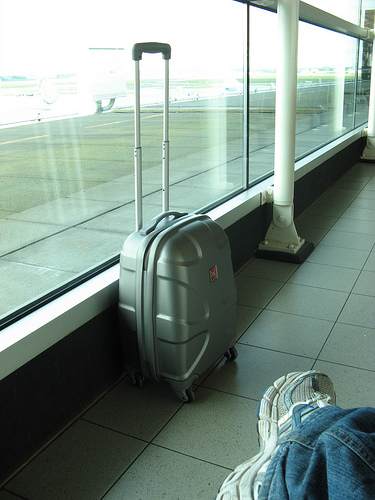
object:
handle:
[139, 209, 192, 234]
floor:
[243, 242, 320, 402]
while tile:
[272, 279, 348, 326]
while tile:
[329, 199, 368, 237]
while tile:
[146, 403, 239, 462]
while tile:
[319, 240, 365, 290]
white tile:
[325, 189, 358, 232]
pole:
[251, 3, 313, 262]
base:
[253, 242, 315, 264]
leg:
[284, 406, 374, 498]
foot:
[215, 369, 334, 499]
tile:
[272, 284, 298, 316]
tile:
[214, 269, 286, 311]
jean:
[250, 404, 374, 500]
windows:
[0, 1, 372, 336]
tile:
[100, 441, 234, 497]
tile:
[2, 418, 150, 497]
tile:
[148, 385, 264, 470]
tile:
[80, 371, 187, 443]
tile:
[199, 342, 317, 400]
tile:
[186, 112, 239, 183]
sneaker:
[204, 367, 342, 499]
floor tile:
[234, 297, 262, 340]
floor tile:
[265, 286, 346, 320]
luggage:
[116, 211, 238, 401]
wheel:
[224, 347, 239, 360]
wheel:
[183, 387, 196, 403]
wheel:
[127, 370, 140, 386]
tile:
[77, 370, 200, 443]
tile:
[233, 299, 346, 360]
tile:
[259, 269, 359, 323]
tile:
[279, 246, 369, 302]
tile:
[298, 230, 373, 280]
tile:
[320, 187, 366, 220]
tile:
[100, 438, 241, 498]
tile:
[318, 321, 373, 370]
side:
[155, 359, 319, 496]